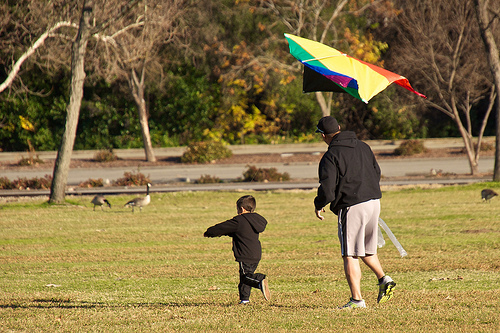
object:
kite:
[283, 30, 429, 104]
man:
[315, 115, 398, 310]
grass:
[3, 184, 500, 331]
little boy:
[202, 194, 271, 303]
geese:
[89, 182, 153, 210]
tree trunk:
[45, 0, 97, 206]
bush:
[181, 136, 231, 164]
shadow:
[0, 297, 342, 308]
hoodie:
[313, 137, 381, 208]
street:
[0, 136, 500, 197]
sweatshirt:
[202, 212, 267, 260]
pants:
[235, 262, 266, 298]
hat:
[314, 118, 343, 132]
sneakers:
[342, 274, 396, 308]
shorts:
[337, 198, 378, 258]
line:
[339, 204, 349, 257]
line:
[238, 261, 261, 284]